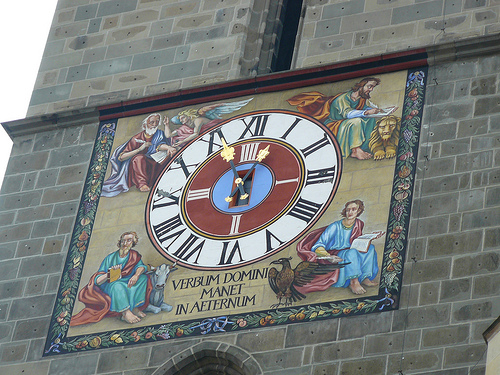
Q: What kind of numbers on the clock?
A: Roman numerals.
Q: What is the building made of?
A: Bricks.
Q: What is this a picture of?
A: Clock.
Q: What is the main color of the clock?
A: White.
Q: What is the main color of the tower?
A: Gray.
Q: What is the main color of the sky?
A: White.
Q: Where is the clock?
A: Side of the building.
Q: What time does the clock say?
A: 12:55.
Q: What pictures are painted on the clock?
A: Religious photos.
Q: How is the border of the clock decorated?
A: Flowers and leaves.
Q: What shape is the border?
A: Square.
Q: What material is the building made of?
A: Brick.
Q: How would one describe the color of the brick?
A: Gray.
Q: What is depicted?
A: A clock.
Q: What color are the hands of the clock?
A: Black.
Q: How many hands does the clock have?
A: Two.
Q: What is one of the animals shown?
A: A lion.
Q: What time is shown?
A: 12:55.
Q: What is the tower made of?
A: Brick.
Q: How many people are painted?
A: 4.